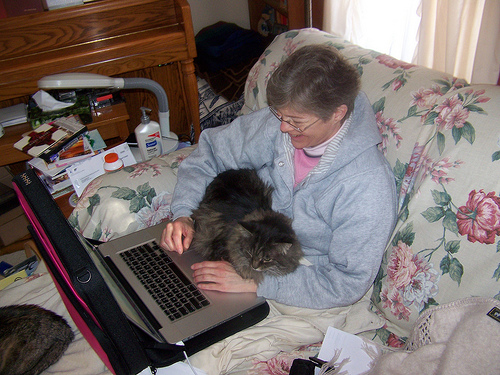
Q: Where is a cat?
A: On woman's lap.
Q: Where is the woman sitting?
A: On a couch.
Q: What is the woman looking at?
A: Laptop computer.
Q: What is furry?
A: The cat.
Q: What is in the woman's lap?
A: A grey cat.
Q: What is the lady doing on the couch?
A: Using a laptop.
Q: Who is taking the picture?
A: A friend.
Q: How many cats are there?
A: 1 cat.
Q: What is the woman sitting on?
A: A flower printed couch.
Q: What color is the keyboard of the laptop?
A: Black.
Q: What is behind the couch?
A: A window.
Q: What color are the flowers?
A: Pink.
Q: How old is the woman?
A: Middle aged.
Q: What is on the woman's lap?
A: Cat.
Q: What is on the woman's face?
A: Glasses.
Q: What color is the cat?
A: Grey.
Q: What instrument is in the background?
A: Piano.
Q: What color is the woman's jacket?
A: Blue.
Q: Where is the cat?
A: Woman's lap.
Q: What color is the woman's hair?
A: Grey.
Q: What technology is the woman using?
A: Laptop.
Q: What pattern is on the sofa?
A: Flowers.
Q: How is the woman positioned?
A: Sitting.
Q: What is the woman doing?
A: Using her laptop.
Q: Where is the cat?
A: On her lap.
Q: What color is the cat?
A: Gray and Black.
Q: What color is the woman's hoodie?
A: Gray.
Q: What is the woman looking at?
A: Laptop screen.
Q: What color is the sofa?
A: Floral beige.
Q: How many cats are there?
A: One.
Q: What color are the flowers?
A: Pink.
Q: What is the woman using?
A: A laptop.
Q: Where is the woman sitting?
A: On a sofa.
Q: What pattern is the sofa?
A: Floral.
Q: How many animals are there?
A: Two.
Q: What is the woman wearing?
A: A hoodie.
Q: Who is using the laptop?
A: An old lady.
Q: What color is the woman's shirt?
A: Pink.